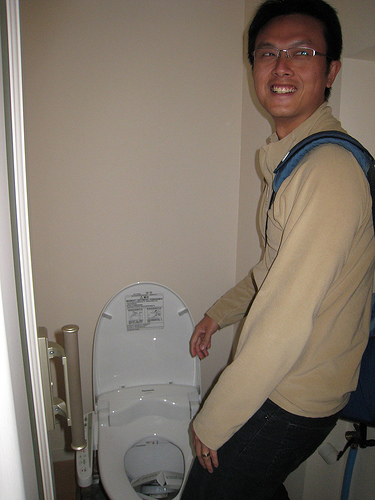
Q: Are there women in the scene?
A: No, there are no women.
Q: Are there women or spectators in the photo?
A: No, there are no women or spectators.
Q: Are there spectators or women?
A: No, there are no women or spectators.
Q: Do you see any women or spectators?
A: No, there are no women or spectators.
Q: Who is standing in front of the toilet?
A: The man is standing in front of the toilet.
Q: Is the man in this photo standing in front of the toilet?
A: Yes, the man is standing in front of the toilet.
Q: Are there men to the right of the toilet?
A: Yes, there is a man to the right of the toilet.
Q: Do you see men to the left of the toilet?
A: No, the man is to the right of the toilet.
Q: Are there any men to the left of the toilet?
A: No, the man is to the right of the toilet.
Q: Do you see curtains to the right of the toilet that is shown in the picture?
A: No, there is a man to the right of the toilet.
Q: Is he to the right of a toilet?
A: Yes, the man is to the right of a toilet.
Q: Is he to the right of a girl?
A: No, the man is to the right of a toilet.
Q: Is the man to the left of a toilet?
A: No, the man is to the right of a toilet.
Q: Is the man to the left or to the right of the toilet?
A: The man is to the right of the toilet.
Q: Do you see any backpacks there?
A: Yes, there is a backpack.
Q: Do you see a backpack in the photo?
A: Yes, there is a backpack.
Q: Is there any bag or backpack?
A: Yes, there is a backpack.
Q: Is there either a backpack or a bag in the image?
A: Yes, there is a backpack.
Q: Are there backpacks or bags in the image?
A: Yes, there is a backpack.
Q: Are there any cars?
A: No, there are no cars.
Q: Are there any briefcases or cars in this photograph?
A: No, there are no cars or briefcases.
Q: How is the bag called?
A: The bag is a backpack.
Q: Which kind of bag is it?
A: The bag is a backpack.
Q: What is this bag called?
A: This is a backpack.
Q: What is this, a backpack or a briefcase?
A: This is a backpack.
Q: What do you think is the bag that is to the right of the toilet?
A: The bag is a backpack.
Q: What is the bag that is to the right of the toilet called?
A: The bag is a backpack.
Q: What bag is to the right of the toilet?
A: The bag is a backpack.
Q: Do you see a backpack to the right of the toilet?
A: Yes, there is a backpack to the right of the toilet.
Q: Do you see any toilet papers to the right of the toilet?
A: No, there is a backpack to the right of the toilet.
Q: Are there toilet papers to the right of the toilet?
A: No, there is a backpack to the right of the toilet.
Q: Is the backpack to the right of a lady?
A: No, the backpack is to the right of the toilet.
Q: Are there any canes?
A: No, there are no canes.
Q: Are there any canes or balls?
A: No, there are no canes or balls.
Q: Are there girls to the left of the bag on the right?
A: No, there is a toilet to the left of the backpack.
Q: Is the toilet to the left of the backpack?
A: Yes, the toilet is to the left of the backpack.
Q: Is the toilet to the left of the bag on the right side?
A: Yes, the toilet is to the left of the backpack.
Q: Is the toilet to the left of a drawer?
A: No, the toilet is to the left of the backpack.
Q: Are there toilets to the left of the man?
A: Yes, there is a toilet to the left of the man.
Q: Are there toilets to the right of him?
A: No, the toilet is to the left of the man.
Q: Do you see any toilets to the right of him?
A: No, the toilet is to the left of the man.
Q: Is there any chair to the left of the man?
A: No, there is a toilet to the left of the man.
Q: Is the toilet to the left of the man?
A: Yes, the toilet is to the left of the man.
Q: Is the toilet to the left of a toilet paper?
A: No, the toilet is to the left of the man.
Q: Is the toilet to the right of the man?
A: No, the toilet is to the left of the man.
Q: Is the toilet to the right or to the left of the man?
A: The toilet is to the left of the man.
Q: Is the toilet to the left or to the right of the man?
A: The toilet is to the left of the man.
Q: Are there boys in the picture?
A: No, there are no boys.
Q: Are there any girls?
A: No, there are no girls.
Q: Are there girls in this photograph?
A: No, there are no girls.